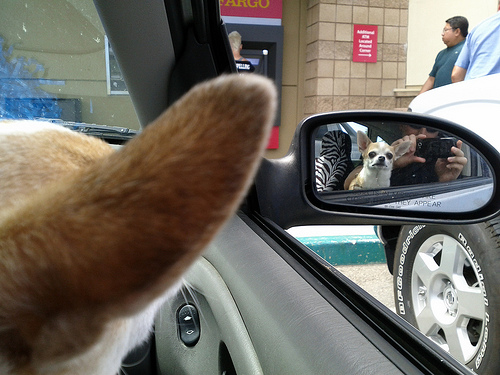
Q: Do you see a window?
A: Yes, there is a window.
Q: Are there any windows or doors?
A: Yes, there is a window.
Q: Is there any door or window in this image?
A: Yes, there is a window.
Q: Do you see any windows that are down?
A: Yes, there is a window that is down.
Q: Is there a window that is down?
A: Yes, there is a window that is down.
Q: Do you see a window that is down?
A: Yes, there is a window that is down.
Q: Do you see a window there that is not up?
A: Yes, there is a window that is down .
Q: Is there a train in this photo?
A: No, there are no trains.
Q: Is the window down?
A: Yes, the window is down.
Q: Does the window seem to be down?
A: Yes, the window is down.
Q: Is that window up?
A: No, the window is down.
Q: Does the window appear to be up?
A: No, the window is down.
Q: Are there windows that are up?
A: No, there is a window but it is down.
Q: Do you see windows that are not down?
A: No, there is a window but it is down.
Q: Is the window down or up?
A: The window is down.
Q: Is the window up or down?
A: The window is down.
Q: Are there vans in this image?
A: No, there are no vans.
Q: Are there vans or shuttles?
A: No, there are no vans or shuttles.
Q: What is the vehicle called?
A: The vehicle is a car.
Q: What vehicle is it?
A: The vehicle is a car.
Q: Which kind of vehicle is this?
A: That is a car.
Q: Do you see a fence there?
A: No, there are no fences.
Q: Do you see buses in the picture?
A: No, there are no buses.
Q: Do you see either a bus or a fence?
A: No, there are no buses or fences.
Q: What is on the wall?
A: The sign is on the wall.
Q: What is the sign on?
A: The sign is on the wall.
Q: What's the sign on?
A: The sign is on the wall.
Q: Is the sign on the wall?
A: Yes, the sign is on the wall.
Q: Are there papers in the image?
A: No, there are no papers.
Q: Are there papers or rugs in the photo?
A: No, there are no papers or rugs.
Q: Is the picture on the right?
A: Yes, the picture is on the right of the image.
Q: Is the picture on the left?
A: No, the picture is on the right of the image.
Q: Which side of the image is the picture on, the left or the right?
A: The picture is on the right of the image.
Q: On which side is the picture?
A: The picture is on the right of the image.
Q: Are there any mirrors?
A: Yes, there is a mirror.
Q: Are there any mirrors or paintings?
A: Yes, there is a mirror.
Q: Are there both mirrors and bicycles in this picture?
A: No, there is a mirror but no bicycles.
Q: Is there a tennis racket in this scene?
A: No, there are no rackets.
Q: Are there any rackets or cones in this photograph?
A: No, there are no rackets or cones.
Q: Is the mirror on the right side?
A: Yes, the mirror is on the right of the image.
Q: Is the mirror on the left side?
A: No, the mirror is on the right of the image.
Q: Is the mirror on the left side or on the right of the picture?
A: The mirror is on the right of the image.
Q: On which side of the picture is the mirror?
A: The mirror is on the right of the image.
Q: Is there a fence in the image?
A: No, there are no fences.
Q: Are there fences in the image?
A: No, there are no fences.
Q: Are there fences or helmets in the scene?
A: No, there are no fences or helmets.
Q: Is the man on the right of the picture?
A: Yes, the man is on the right of the image.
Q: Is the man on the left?
A: No, the man is on the right of the image.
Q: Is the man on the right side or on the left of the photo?
A: The man is on the right of the image.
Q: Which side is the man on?
A: The man is on the right of the image.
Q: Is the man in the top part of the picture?
A: Yes, the man is in the top of the image.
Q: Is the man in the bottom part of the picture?
A: No, the man is in the top of the image.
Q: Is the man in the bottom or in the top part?
A: The man is in the top of the image.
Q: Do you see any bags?
A: No, there are no bags.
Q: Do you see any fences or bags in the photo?
A: No, there are no bags or fences.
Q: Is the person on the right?
A: Yes, the person is on the right of the image.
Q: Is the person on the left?
A: No, the person is on the right of the image.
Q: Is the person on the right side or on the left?
A: The person is on the right of the image.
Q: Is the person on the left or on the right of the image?
A: The person is on the right of the image.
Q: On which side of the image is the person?
A: The person is on the right of the image.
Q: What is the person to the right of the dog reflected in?
A: The person is reflected in the mirror.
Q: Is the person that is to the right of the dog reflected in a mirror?
A: Yes, the person is reflected in a mirror.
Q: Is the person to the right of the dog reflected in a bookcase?
A: No, the person is reflected in a mirror.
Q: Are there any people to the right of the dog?
A: Yes, there is a person to the right of the dog.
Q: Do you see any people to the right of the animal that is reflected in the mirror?
A: Yes, there is a person to the right of the dog.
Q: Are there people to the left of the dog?
A: No, the person is to the right of the dog.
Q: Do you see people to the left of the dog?
A: No, the person is to the right of the dog.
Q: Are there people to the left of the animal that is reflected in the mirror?
A: No, the person is to the right of the dog.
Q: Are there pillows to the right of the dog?
A: No, there is a person to the right of the dog.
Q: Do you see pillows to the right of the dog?
A: No, there is a person to the right of the dog.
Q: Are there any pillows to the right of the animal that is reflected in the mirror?
A: No, there is a person to the right of the dog.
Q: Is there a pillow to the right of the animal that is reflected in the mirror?
A: No, there is a person to the right of the dog.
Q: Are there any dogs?
A: Yes, there is a dog.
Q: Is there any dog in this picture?
A: Yes, there is a dog.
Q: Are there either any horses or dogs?
A: Yes, there is a dog.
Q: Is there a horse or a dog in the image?
A: Yes, there is a dog.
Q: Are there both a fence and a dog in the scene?
A: No, there is a dog but no fences.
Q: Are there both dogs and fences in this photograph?
A: No, there is a dog but no fences.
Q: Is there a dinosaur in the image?
A: No, there are no dinosaurs.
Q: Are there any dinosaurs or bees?
A: No, there are no dinosaurs or bees.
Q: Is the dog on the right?
A: Yes, the dog is on the right of the image.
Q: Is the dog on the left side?
A: No, the dog is on the right of the image.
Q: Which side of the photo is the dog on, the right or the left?
A: The dog is on the right of the image.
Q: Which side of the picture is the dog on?
A: The dog is on the right of the image.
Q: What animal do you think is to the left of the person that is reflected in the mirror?
A: The animal is a dog.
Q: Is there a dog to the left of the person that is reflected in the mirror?
A: Yes, there is a dog to the left of the person.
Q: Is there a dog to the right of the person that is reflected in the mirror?
A: No, the dog is to the left of the person.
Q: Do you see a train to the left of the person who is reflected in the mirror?
A: No, there is a dog to the left of the person.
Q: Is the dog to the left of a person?
A: Yes, the dog is to the left of a person.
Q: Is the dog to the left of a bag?
A: No, the dog is to the left of a person.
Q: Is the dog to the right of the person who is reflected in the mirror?
A: No, the dog is to the left of the person.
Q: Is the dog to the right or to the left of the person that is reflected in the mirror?
A: The dog is to the left of the person.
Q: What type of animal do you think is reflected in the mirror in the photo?
A: The animal is a dog.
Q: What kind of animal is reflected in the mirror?
A: The animal is a dog.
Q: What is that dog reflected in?
A: The dog is reflected in the mirror.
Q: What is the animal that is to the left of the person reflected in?
A: The dog is reflected in the mirror.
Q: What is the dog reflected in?
A: The dog is reflected in the mirror.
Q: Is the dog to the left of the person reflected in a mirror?
A: Yes, the dog is reflected in a mirror.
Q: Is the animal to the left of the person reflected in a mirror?
A: Yes, the dog is reflected in a mirror.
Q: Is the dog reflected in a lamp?
A: No, the dog is reflected in a mirror.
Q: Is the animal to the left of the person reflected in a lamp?
A: No, the dog is reflected in a mirror.